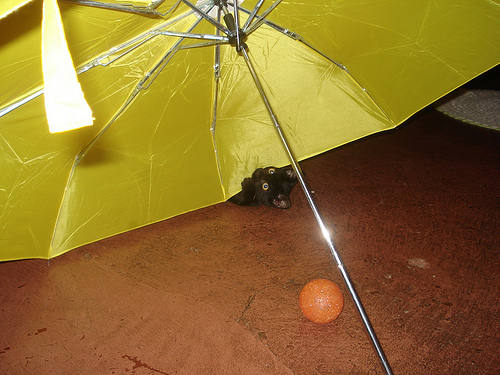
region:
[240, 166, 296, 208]
A cat is under the umbrella.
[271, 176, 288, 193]
The cat is black.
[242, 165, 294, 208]
The cat is a kitten.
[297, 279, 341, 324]
A ball is on the ground.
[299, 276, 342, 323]
The ball is orange.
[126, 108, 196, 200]
The umbrella is yellow.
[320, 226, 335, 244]
Light is reflected on the umbrella's handle.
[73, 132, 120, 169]
A shadow is on the umbrella.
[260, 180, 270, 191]
The cat has yellow eyes.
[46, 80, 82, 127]
A white object hangs from the umbrella.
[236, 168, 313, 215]
this is a cat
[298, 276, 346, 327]
this is a ball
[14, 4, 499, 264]
this is an umbrella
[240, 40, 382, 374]
this is a metallic rod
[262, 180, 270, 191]
this is a cat's eye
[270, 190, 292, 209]
this is a cat's ear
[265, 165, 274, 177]
this is a cat's eye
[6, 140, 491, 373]
this is a floor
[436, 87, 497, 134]
this is a mat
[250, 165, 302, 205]
this is a cat's head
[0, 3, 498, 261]
interior of open umbrella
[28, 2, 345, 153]
metal frame of umbrella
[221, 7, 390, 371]
metal pole of umbrella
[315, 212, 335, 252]
light reflection on metal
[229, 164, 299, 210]
black cat under umbrella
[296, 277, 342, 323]
red ball on ground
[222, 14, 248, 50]
black plastic on pole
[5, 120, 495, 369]
surface of cement floor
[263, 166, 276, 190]
two eyes of cat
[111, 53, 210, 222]
wrinkles in umbrella fabric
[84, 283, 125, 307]
this is the floor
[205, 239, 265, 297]
the floor is clean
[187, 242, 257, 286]
the floor is brown in color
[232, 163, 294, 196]
the cat is small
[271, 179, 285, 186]
the fur is black in color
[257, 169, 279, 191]
these are the eyes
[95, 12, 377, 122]
this is an umbrella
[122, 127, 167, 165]
the umbrella is yellow in color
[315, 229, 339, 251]
the metal is shiny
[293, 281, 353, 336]
orange ball on ground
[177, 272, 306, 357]
dark spots on floor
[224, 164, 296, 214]
cat under umbrella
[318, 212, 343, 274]
reflection on the pole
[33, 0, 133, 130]
tag on the umbrella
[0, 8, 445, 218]
umbrella is yellow and large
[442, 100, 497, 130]
rug in the corner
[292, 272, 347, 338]
ball is small and orange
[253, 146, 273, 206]
cat's eyes are green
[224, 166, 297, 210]
small cat is black